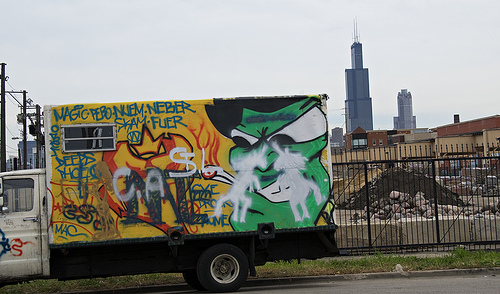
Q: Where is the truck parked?
A: Side of the street.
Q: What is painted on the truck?
A: Graffiti.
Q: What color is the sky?
A: Blue.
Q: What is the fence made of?
A: Metal.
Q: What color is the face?
A: Green.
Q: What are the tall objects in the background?
A: Buildings.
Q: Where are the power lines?
A: Lining the street.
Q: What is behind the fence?
A: A pile of dirt.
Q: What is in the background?
A: A city.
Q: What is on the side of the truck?
A: Graffiti.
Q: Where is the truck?
A: On the street.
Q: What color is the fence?
A: Black.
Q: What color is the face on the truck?
A: Green.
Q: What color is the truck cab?
A: White.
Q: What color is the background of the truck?
A: Yellow.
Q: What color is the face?
A: Green.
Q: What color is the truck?
A: White.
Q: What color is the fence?
A: Black.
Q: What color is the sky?
A: White.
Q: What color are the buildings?
A: Brown.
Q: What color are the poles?
A: Black.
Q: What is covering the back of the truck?
A: Graffiti.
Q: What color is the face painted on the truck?
A: Green.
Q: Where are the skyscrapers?
A: To the right, behind the fence.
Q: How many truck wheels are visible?
A: One.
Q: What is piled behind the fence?
A: Rubble.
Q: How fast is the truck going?
A: It is parked.